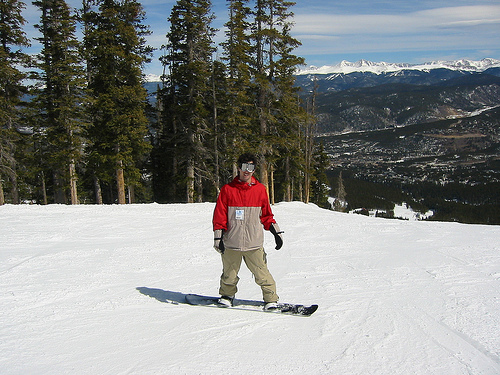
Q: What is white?
A: Snow.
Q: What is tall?
A: Pine trees.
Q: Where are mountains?
A: In the distance.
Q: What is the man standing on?
A: Snowboard.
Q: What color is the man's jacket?
A: Red and beige.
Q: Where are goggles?
A: On man's face.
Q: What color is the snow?
A: White.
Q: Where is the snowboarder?
A: On the snow.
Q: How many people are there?
A: One.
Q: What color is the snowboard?
A: Black.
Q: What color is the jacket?
A: Red and gray.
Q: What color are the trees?
A: Green.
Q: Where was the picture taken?
A: On a mountain slope.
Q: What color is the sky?
A: Blue.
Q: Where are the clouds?
A: In the sky.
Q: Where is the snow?
A: On ground.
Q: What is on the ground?
A: Snow.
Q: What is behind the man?
A: Trees.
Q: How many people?
A: 1.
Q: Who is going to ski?
A: The man.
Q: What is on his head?
A: Goggles.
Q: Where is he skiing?
A: Down the mountain.